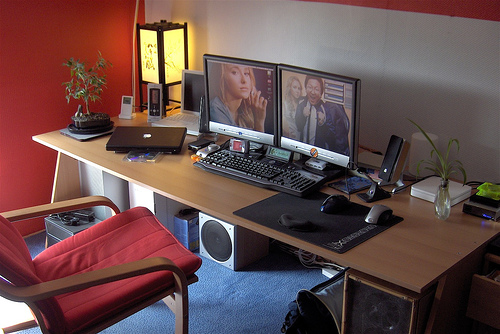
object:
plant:
[401, 113, 473, 224]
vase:
[429, 182, 456, 223]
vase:
[62, 111, 121, 138]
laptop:
[101, 114, 195, 157]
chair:
[0, 192, 212, 334]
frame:
[76, 252, 188, 292]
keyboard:
[188, 148, 328, 199]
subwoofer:
[374, 130, 417, 191]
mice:
[358, 202, 396, 226]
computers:
[190, 49, 365, 200]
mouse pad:
[228, 180, 408, 257]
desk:
[19, 110, 500, 296]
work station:
[14, 121, 500, 309]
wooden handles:
[0, 194, 125, 223]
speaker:
[197, 94, 207, 135]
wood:
[112, 167, 150, 181]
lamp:
[130, 15, 192, 91]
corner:
[141, 6, 149, 19]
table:
[27, 97, 500, 305]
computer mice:
[316, 192, 356, 215]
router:
[404, 170, 476, 210]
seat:
[0, 188, 212, 334]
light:
[123, 15, 199, 91]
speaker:
[195, 208, 276, 279]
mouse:
[356, 199, 396, 228]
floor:
[0, 219, 328, 333]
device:
[120, 181, 176, 236]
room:
[0, 0, 500, 334]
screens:
[274, 61, 368, 171]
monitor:
[200, 54, 275, 143]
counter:
[24, 93, 500, 297]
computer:
[145, 65, 205, 137]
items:
[100, 45, 423, 233]